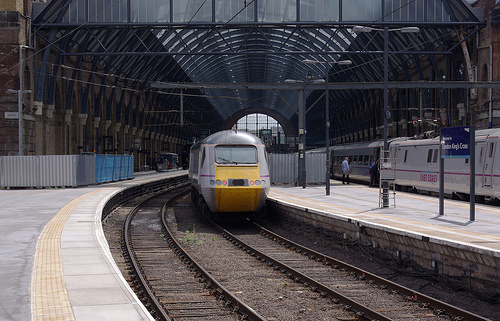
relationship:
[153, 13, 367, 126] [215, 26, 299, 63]
roof has panes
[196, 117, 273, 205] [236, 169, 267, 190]
train with light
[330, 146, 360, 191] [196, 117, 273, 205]
man inside train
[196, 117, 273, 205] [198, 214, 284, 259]
train on railway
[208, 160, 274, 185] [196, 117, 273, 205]
number in train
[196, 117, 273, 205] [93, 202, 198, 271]
train has track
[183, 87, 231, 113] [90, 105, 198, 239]
cable at platform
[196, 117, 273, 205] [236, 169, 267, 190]
train has light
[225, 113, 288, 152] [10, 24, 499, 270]
window showing city